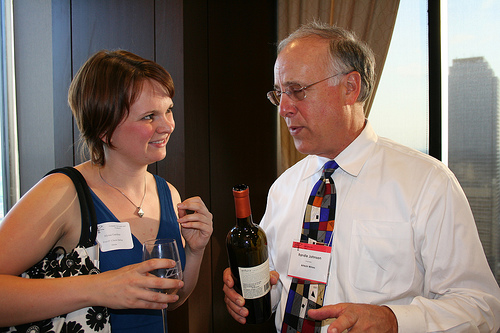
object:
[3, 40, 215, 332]
woman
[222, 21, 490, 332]
man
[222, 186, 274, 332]
bottle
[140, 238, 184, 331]
glass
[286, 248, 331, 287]
nametag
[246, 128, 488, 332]
shirt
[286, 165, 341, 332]
tie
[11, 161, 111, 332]
purse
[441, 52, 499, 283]
building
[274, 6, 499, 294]
window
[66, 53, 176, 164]
hair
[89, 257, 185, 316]
hand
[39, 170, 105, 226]
shoulder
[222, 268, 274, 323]
hand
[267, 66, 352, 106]
glasses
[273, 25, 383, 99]
hair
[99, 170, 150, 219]
necklace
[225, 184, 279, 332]
wine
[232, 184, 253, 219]
neck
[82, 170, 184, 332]
dress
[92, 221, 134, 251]
sticker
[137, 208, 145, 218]
charm